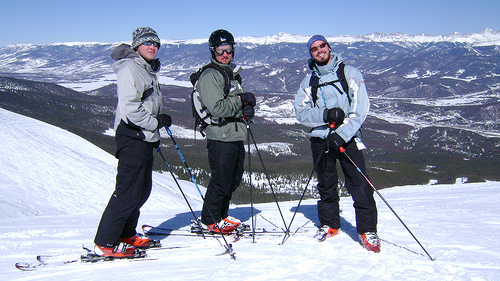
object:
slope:
[1, 108, 500, 278]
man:
[188, 29, 265, 234]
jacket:
[191, 61, 252, 142]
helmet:
[206, 29, 234, 45]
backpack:
[189, 67, 234, 128]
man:
[291, 33, 390, 255]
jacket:
[288, 54, 372, 143]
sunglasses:
[310, 42, 326, 52]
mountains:
[3, 25, 499, 94]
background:
[445, 37, 496, 43]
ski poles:
[335, 138, 435, 262]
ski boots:
[198, 219, 250, 234]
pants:
[200, 139, 253, 222]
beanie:
[307, 34, 329, 48]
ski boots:
[89, 241, 145, 256]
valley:
[2, 73, 498, 190]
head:
[207, 29, 235, 65]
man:
[92, 25, 176, 253]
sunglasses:
[140, 41, 160, 47]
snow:
[136, 250, 443, 271]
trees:
[260, 173, 307, 190]